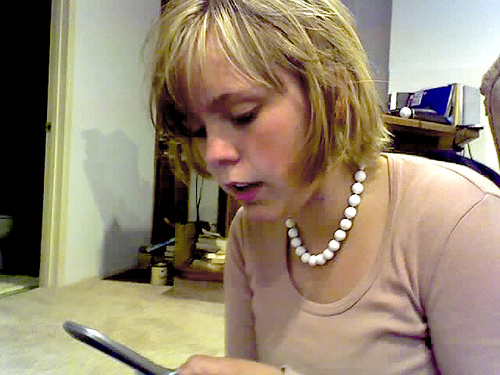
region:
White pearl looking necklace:
[283, 222, 341, 270]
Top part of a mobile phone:
[55, 308, 172, 373]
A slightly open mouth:
[220, 173, 274, 207]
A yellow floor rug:
[122, 301, 206, 344]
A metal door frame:
[37, 25, 69, 211]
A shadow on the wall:
[81, 117, 157, 279]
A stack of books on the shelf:
[187, 217, 225, 287]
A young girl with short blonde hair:
[145, 0, 390, 227]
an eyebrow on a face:
[208, 83, 245, 106]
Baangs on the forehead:
[152, 18, 308, 88]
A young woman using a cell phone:
[42, 0, 441, 374]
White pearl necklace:
[275, 136, 374, 266]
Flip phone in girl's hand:
[56, 316, 180, 373]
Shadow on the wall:
[78, 111, 160, 276]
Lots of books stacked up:
[136, 209, 251, 307]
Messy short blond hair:
[152, 2, 395, 175]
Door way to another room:
[2, 2, 74, 290]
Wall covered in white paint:
[355, 2, 498, 183]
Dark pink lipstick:
[213, 177, 274, 212]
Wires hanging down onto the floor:
[184, 165, 205, 278]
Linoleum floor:
[2, 275, 201, 372]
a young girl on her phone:
[75, 8, 475, 373]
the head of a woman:
[134, 2, 354, 220]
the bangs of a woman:
[185, 13, 263, 75]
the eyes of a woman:
[167, 99, 264, 134]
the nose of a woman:
[198, 131, 240, 165]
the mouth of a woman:
[222, 175, 257, 195]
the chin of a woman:
[232, 193, 274, 224]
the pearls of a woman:
[282, 222, 353, 277]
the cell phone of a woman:
[70, 315, 164, 373]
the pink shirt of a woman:
[230, 218, 495, 365]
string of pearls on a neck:
[256, 162, 425, 310]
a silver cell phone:
[45, 279, 216, 374]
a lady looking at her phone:
[39, 9, 480, 373]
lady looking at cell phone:
[29, 4, 469, 373]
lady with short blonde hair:
[105, 4, 451, 291]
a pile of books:
[142, 214, 229, 307]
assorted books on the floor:
[148, 197, 255, 332]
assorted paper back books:
[133, 197, 285, 332]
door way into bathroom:
[1, 16, 71, 301]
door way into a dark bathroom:
[0, 4, 87, 365]